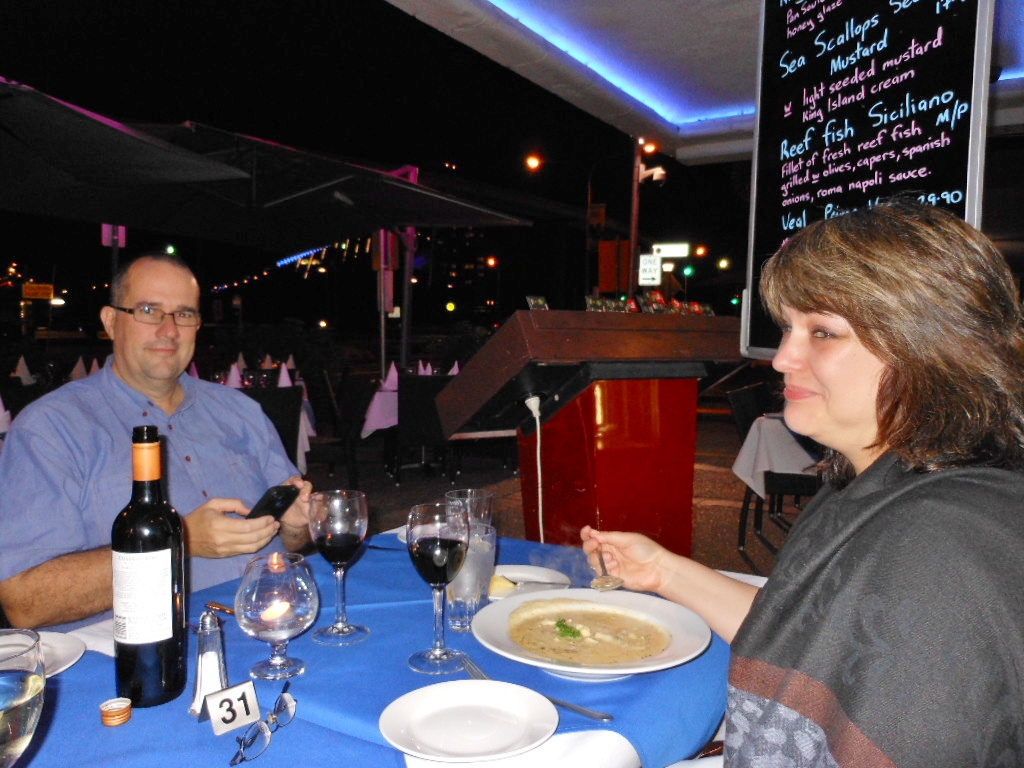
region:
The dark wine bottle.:
[116, 427, 190, 706]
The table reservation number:
[207, 677, 256, 736]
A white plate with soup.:
[471, 586, 710, 686]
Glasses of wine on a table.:
[237, 487, 469, 674]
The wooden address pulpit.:
[438, 310, 748, 552]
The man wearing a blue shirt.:
[0, 256, 304, 629]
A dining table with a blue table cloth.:
[0, 528, 737, 766]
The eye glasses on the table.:
[224, 680, 297, 761]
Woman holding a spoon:
[577, 192, 1020, 763]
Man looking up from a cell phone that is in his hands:
[3, 249, 349, 642]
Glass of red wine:
[398, 507, 475, 682]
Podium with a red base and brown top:
[432, 280, 747, 563]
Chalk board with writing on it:
[738, 0, 1001, 368]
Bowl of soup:
[467, 564, 715, 694]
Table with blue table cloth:
[15, 520, 756, 765]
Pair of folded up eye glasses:
[230, 682, 317, 765]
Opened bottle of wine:
[113, 425, 196, 716]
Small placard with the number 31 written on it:
[196, 682, 269, 741]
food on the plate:
[541, 613, 644, 662]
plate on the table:
[408, 680, 555, 745]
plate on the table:
[665, 628, 719, 692]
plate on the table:
[48, 628, 118, 661]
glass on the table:
[333, 619, 372, 655]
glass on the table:
[273, 610, 318, 678]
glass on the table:
[187, 606, 242, 704]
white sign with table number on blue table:
[198, 682, 257, 731]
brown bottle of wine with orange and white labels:
[109, 428, 186, 708]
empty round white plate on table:
[377, 677, 555, 758]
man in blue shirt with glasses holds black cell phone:
[0, 255, 322, 632]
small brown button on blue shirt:
[182, 451, 192, 465]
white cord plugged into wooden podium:
[526, 391, 540, 541]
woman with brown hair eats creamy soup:
[576, 210, 1022, 767]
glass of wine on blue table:
[400, 498, 467, 675]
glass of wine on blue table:
[307, 489, 366, 639]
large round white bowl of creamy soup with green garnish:
[468, 583, 713, 685]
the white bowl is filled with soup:
[475, 574, 706, 683]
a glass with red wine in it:
[406, 502, 471, 673]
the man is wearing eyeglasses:
[100, 258, 200, 391]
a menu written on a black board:
[753, 7, 976, 245]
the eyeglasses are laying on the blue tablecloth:
[225, 686, 311, 763]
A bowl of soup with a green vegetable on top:
[473, 585, 717, 688]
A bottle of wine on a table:
[104, 411, 196, 709]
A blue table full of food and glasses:
[0, 535, 746, 766]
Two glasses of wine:
[294, 487, 473, 671]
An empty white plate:
[368, 680, 561, 763]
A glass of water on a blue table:
[447, 513, 508, 609]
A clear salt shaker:
[186, 604, 237, 715]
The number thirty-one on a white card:
[202, 689, 264, 738]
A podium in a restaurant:
[432, 304, 718, 567]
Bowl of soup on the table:
[463, 588, 720, 681]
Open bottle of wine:
[106, 410, 195, 720]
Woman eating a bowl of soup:
[474, 212, 1019, 766]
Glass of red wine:
[401, 479, 472, 675]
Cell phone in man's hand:
[185, 472, 313, 559]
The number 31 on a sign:
[208, 670, 263, 741]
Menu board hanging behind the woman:
[732, 0, 1002, 359]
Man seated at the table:
[2, 253, 317, 650]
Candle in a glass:
[236, 537, 325, 674]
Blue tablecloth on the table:
[0, 535, 746, 752]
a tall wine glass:
[389, 499, 475, 671]